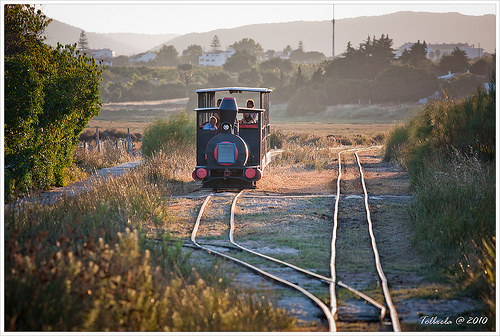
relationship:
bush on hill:
[284, 84, 330, 119] [92, 90, 459, 125]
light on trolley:
[222, 116, 233, 143] [187, 77, 285, 190]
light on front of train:
[221, 120, 233, 134] [168, 64, 293, 207]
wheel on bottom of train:
[226, 160, 271, 196] [176, 76, 303, 201]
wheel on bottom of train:
[175, 151, 224, 192] [176, 76, 303, 201]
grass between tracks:
[268, 197, 328, 250] [187, 148, 397, 333]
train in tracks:
[192, 85, 276, 193] [194, 194, 344, 333]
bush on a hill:
[381, 92, 498, 262] [307, 40, 494, 183]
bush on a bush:
[447, 82, 499, 163] [431, 81, 459, 131]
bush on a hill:
[447, 82, 499, 163] [416, 77, 496, 232]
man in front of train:
[200, 114, 224, 132] [191, 85, 272, 187]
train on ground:
[192, 85, 276, 193] [126, 72, 458, 250]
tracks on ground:
[150, 112, 463, 284] [126, 72, 458, 250]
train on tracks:
[183, 67, 266, 176] [187, 148, 397, 333]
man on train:
[200, 114, 224, 132] [191, 85, 272, 187]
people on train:
[244, 100, 259, 120] [191, 85, 272, 187]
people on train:
[241, 110, 254, 122] [191, 85, 272, 187]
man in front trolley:
[198, 111, 223, 131] [191, 84, 273, 191]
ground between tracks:
[234, 195, 334, 278] [190, 189, 386, 320]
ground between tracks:
[234, 195, 334, 278] [329, 147, 401, 334]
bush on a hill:
[4, 9, 94, 172] [7, 130, 480, 328]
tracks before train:
[174, 151, 441, 263] [151, 73, 309, 174]